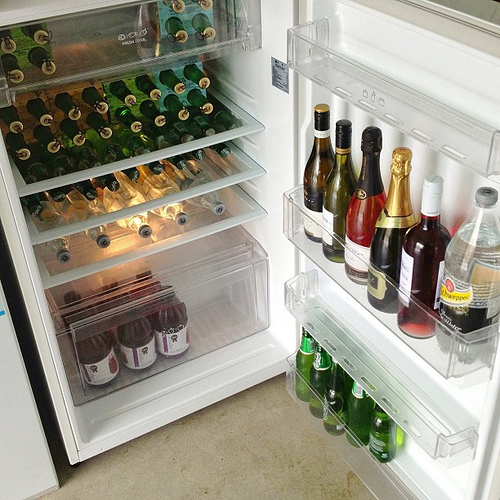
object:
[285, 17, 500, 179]
door shelf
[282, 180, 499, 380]
door shelf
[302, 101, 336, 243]
bottle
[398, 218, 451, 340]
wine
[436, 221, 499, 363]
tonic water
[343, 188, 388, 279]
wine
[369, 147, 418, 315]
wine bottle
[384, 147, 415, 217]
foil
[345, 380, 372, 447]
bottle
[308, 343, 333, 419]
bottle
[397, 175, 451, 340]
bottle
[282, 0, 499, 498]
door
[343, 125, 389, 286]
bottle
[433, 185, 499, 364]
bottle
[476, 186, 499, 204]
cap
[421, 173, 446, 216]
cap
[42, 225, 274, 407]
drawer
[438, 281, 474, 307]
label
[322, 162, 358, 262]
wine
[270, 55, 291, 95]
label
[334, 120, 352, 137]
screw cap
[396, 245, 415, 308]
label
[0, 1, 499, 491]
refrigerator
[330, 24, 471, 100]
empty